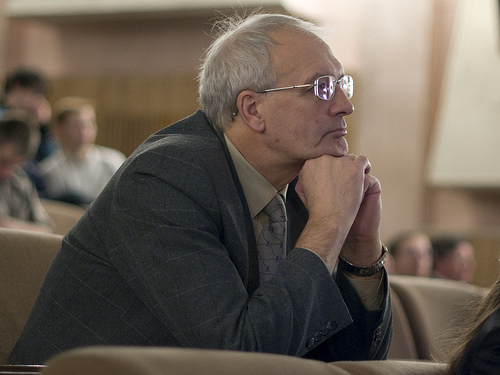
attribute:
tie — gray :
[251, 190, 294, 300]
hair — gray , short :
[197, 21, 292, 126]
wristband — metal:
[338, 254, 398, 277]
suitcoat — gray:
[14, 112, 393, 358]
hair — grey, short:
[198, 11, 271, 109]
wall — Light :
[282, 1, 435, 253]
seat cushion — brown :
[395, 271, 486, 352]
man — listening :
[130, 52, 387, 329]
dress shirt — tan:
[230, 134, 297, 287]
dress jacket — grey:
[1, 107, 391, 371]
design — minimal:
[256, 228, 286, 264]